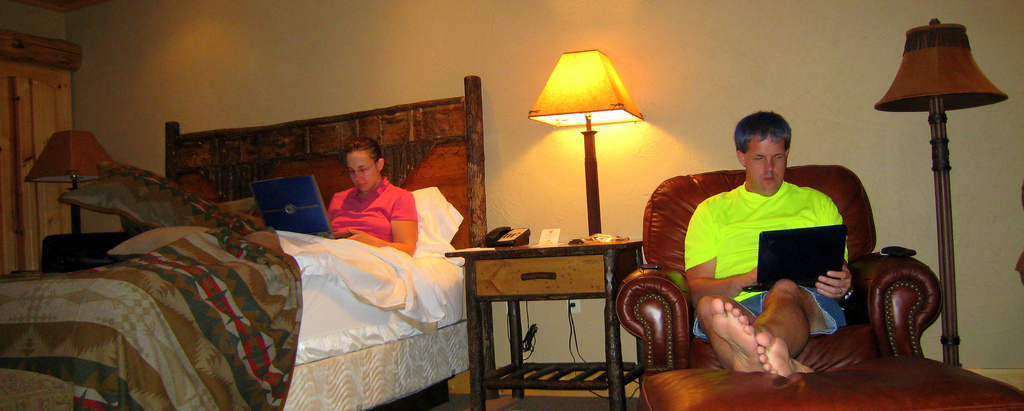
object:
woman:
[322, 142, 428, 241]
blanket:
[0, 171, 308, 410]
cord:
[514, 297, 620, 362]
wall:
[468, 145, 696, 403]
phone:
[484, 226, 533, 247]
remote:
[880, 245, 919, 257]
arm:
[863, 248, 946, 356]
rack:
[473, 360, 642, 391]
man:
[287, 134, 456, 256]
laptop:
[746, 222, 849, 295]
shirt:
[684, 184, 849, 303]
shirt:
[684, 180, 829, 362]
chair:
[621, 167, 946, 377]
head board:
[161, 77, 489, 248]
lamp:
[526, 48, 646, 241]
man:
[681, 109, 857, 378]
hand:
[818, 262, 855, 298]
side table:
[443, 234, 645, 407]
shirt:
[677, 180, 852, 299]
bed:
[5, 72, 500, 407]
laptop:
[249, 177, 335, 237]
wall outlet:
[564, 300, 581, 311]